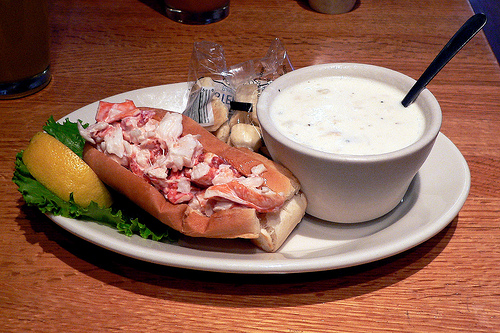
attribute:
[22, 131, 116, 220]
lemon wedge — yellow, garnish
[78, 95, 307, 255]
lobster sandwich — pink, filled, large, chunky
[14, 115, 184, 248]
lettuce — green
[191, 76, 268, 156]
crackers — packaged, in plastic, in package, bagged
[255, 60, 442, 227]
bowl — white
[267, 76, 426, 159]
soup — white, clam chowder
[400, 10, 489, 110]
spoon — silver, submerged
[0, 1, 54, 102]
glass — customer drink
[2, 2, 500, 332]
table — wooden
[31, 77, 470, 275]
plate — round, white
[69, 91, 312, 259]
roll — white, bread